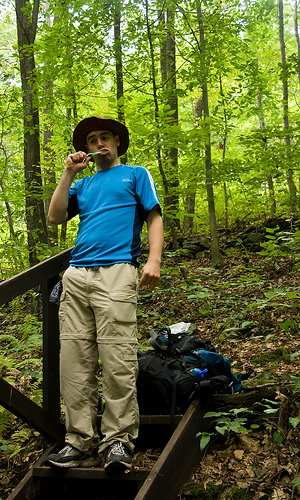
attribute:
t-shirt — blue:
[66, 163, 160, 267]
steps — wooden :
[47, 405, 122, 494]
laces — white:
[59, 443, 73, 458]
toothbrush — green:
[80, 150, 105, 161]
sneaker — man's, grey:
[43, 443, 102, 467]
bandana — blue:
[47, 278, 65, 304]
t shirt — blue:
[58, 161, 162, 271]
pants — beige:
[57, 264, 144, 453]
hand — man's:
[66, 147, 89, 174]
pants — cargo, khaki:
[52, 253, 152, 451]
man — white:
[69, 116, 137, 257]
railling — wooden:
[0, 240, 74, 312]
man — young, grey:
[46, 116, 162, 472]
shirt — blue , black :
[40, 147, 177, 261]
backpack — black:
[137, 320, 241, 421]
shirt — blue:
[87, 190, 124, 247]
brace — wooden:
[9, 383, 58, 429]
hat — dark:
[72, 121, 118, 131]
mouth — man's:
[92, 147, 111, 156]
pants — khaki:
[51, 260, 139, 452]